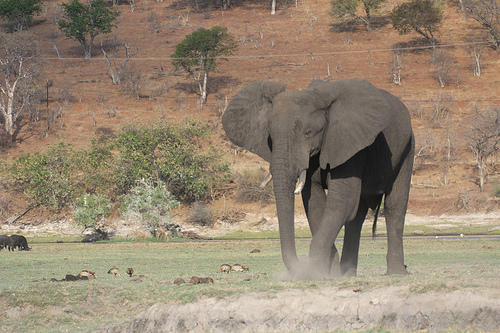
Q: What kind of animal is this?
A: Elephant.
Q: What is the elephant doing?
A: Walking.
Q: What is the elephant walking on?
A: Grass.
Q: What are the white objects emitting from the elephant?
A: Tusks.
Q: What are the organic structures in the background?
A: Trees and hills.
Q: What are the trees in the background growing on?
A: Hill.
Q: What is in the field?
A: Elephant.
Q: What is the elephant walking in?
A: Dirt.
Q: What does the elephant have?
A: Tusks.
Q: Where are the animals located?
A: Field.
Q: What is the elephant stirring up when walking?
A: Dust.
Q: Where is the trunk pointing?
A: To the ground.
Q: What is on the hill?
A: Brush.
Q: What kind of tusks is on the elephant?
A: Ivory.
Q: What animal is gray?
A: Elephant.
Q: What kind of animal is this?
A: Elephant.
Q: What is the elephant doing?
A: Walking.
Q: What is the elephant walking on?
A: Grass.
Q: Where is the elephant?
A: Field of grass.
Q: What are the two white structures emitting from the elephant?
A: Tusks.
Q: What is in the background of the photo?
A: Trees, foliiage and hills.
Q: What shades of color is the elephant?
A: Grey and brown.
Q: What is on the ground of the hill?
A: Grass and trees.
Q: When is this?
A: Daytime.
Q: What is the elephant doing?
A: Walking.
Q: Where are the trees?
A: On the hillside.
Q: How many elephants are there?
A: One.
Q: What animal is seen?
A: Elephant.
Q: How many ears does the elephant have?
A: Two.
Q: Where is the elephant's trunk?
A: On the ground.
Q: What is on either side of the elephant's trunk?
A: Tusks.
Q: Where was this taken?
A: A prairie.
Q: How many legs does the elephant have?
A: Four.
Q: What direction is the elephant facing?
A: Left.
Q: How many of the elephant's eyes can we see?
A: One.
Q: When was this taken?
A: In a summer day.